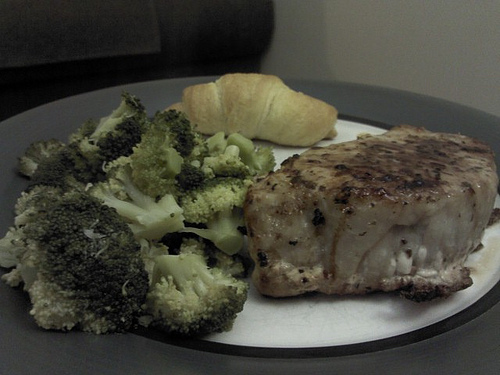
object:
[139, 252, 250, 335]
broccoli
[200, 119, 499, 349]
plate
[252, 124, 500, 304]
meat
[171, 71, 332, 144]
croissant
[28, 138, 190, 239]
broccoli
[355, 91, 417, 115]
rim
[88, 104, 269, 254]
food types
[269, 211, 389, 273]
fat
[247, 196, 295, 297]
edge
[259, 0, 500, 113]
wall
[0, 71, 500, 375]
table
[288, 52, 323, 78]
shadow